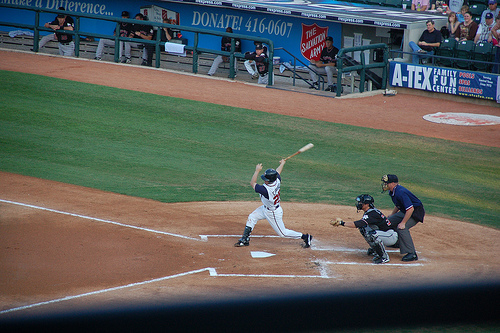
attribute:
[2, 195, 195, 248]
base line — chalk, white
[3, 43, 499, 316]
field — brown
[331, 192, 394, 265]
catcher — crouching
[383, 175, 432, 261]
umpire — crouching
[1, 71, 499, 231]
grass — foul territory, cut, green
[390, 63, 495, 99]
advertisement — blue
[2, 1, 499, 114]
stands — green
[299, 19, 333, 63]
logo — red, white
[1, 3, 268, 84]
fence — green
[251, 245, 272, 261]
home plate — white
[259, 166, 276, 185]
helmet — black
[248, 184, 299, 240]
uniform — white, blue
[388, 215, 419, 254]
pants — grey